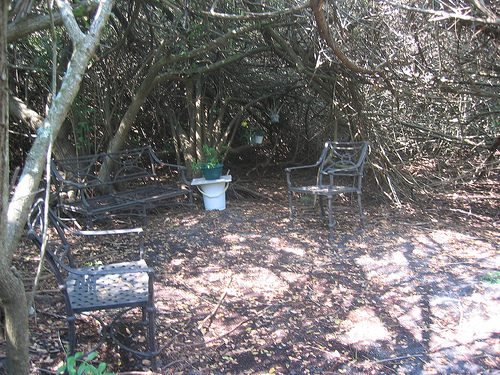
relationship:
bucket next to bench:
[175, 157, 262, 227] [48, 147, 200, 229]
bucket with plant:
[201, 183, 228, 211] [188, 143, 225, 181]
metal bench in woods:
[33, 203, 170, 343] [64, 32, 444, 332]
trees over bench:
[160, 48, 256, 130] [48, 147, 200, 229]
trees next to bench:
[2, 3, 486, 203] [276, 129, 388, 236]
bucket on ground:
[201, 183, 228, 211] [41, 200, 461, 371]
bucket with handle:
[201, 183, 228, 211] [192, 182, 225, 195]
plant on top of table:
[187, 134, 231, 175] [183, 165, 237, 215]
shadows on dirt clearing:
[150, 210, 450, 372] [68, 189, 498, 370]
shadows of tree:
[150, 210, 450, 372] [3, 6, 498, 360]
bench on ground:
[284, 141, 372, 241] [2, 173, 498, 373]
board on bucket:
[191, 174, 233, 183] [202, 182, 225, 211]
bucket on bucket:
[200, 164, 224, 180] [196, 181, 231, 206]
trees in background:
[4, 5, 496, 225] [3, 3, 499, 293]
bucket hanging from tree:
[254, 135, 264, 144] [213, 84, 310, 180]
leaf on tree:
[35, 124, 52, 140] [0, 0, 116, 374]